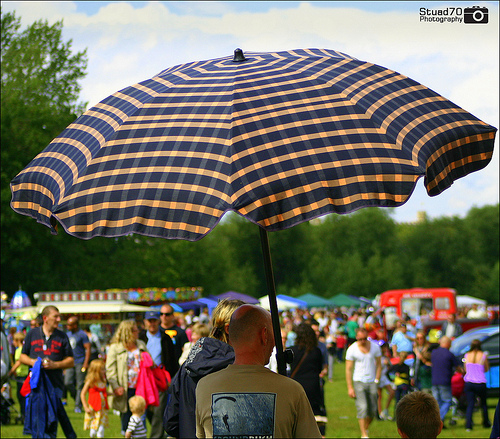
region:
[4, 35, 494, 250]
an umbrella with orange dots.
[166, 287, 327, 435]
a man in a yellow shirt.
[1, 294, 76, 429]
a man carrying a jacket.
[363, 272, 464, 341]
a red bus near a crowd of people.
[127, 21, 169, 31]
a section of a cloudy blue sky.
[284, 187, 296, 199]
an orange dot on an umbrella.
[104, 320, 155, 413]
a woman with blonde hair.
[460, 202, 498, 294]
a section of a green forest.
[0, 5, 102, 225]
a forest of green trees.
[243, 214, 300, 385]
a handle on an umbrella.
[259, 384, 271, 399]
part of a back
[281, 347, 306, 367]
part of an umbrella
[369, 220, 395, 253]
part of a tree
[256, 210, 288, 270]
part of an umbrella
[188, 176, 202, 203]
part of an umbrella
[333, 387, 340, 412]
part of a lawn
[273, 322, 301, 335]
part of a handle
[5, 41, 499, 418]
A man holding up patio umbrella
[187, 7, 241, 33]
this is the sky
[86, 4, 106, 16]
the sky is blue in color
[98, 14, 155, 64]
the sky has clouds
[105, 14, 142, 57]
the clouds are white in color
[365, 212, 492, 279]
these are some trees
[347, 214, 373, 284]
the trees are tall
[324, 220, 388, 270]
the leaves are green in color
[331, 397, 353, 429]
this is the grass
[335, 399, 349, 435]
the grass is green in color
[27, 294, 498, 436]
these are some people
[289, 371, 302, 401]
part of a shoulder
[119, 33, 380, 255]
black and yellow umbrella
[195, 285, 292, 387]
head of a man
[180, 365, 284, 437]
back of the person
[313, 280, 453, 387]
blurry people in photo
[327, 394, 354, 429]
green grass on ground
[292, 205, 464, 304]
trees in the distance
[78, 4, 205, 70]
sky above the land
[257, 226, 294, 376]
The rod of the umbrella.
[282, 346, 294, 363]
The knob on the rod of the umbrella.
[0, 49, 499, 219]
The plaid umbrella the man is holding.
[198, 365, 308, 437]
The t-shirt the man holding the umbrella is wearing.